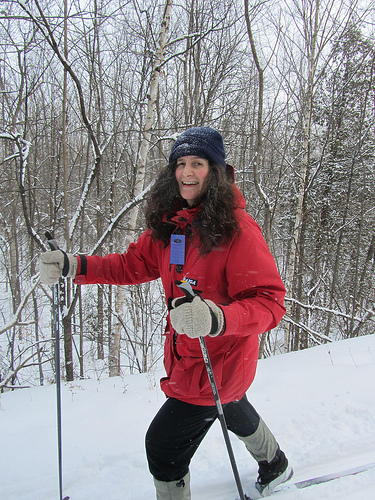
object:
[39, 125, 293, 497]
woman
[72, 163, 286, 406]
coat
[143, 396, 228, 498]
pants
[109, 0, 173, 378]
trees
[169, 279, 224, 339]
gloves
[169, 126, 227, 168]
cap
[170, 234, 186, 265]
tag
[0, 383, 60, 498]
snow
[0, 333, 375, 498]
ground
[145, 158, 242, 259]
hair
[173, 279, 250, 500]
poles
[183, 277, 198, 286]
label